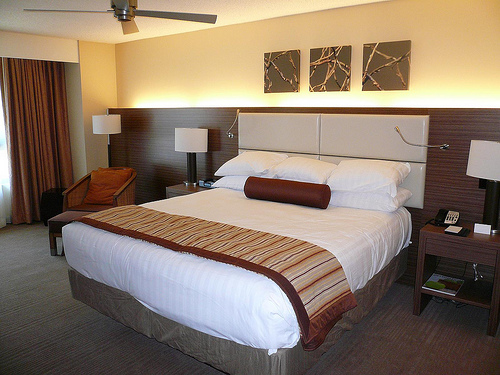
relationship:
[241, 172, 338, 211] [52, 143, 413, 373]
pillow on bed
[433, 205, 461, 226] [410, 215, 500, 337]
telephone on bedside table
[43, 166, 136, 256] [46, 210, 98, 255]
chair with foot rest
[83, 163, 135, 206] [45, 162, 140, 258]
pillows in chair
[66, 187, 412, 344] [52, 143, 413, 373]
sheet on bed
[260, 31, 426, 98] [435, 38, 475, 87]
art on wall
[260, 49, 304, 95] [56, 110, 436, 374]
art above bed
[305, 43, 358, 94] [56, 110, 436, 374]
painting above bed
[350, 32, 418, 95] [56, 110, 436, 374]
painting above bed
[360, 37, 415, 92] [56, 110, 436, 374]
painting above bed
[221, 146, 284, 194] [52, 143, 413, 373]
pillow on bed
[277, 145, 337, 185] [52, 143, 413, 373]
pillow on bed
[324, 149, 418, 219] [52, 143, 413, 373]
pillow on bed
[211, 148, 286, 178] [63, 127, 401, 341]
pillow on bed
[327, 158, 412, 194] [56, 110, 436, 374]
pillow on bed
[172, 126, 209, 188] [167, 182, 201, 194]
lamp on table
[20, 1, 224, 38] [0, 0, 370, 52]
fan on ceiling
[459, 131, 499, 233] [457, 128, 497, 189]
lamp has shade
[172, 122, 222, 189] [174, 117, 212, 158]
lamp has shade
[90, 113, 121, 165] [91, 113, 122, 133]
lamp has shade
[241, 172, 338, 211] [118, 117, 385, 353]
pillow on bed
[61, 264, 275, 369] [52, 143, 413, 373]
skirting on bottom of bed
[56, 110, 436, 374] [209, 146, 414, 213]
bed has pillows.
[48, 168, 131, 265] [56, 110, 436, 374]
chair by bed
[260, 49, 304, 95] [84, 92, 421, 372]
art above bed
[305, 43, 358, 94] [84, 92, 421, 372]
painting above bed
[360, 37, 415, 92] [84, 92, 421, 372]
painting above bed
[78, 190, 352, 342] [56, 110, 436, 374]
blanket on bed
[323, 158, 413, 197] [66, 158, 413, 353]
pillow sitting on bed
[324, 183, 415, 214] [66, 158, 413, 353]
pillow sitting on bed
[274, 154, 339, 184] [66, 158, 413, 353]
pillow sitting on bed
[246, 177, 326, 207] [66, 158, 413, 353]
pillow sitting on bed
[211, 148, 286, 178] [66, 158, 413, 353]
pillow sitting on bed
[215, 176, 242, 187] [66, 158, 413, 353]
pillow sitting on bed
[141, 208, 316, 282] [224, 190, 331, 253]
coverlet on top of sheet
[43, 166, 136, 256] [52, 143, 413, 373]
chair next to bed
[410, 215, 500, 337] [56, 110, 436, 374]
bedside table next to bed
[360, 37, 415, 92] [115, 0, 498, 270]
painting on wall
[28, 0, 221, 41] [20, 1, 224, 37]
blades on fan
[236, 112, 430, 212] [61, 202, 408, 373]
headboard at head of bed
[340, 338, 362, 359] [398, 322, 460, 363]
lines through carpet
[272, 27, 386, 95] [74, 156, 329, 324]
painting above bed